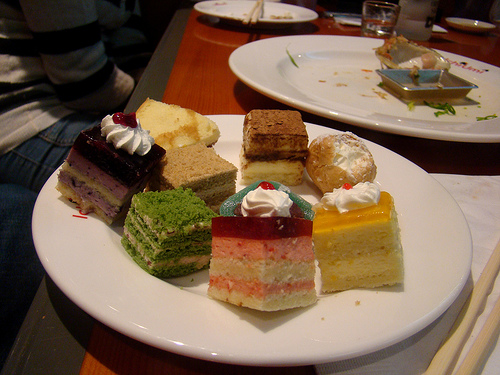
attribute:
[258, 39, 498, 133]
plate — empty, white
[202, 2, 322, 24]
plate — empty, white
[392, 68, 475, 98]
cup — metal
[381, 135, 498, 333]
plate — white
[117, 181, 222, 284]
pettifor — green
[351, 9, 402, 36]
glass — clear, empty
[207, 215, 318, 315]
cake — Red 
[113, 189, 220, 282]
cake — green, layered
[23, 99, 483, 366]
plate — white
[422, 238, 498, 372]
chopstick — wooden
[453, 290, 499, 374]
chopstick — wooden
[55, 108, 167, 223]
pastry — purple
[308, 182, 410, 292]
cake — Yellow 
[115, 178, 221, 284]
dessert — green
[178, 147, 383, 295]
cake — white , Green 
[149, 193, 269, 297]
cake — white, green 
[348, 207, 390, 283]
dessert — yellow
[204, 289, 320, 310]
layer — white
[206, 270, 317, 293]
layer — pink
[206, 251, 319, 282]
layer — white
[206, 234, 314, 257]
layer — pink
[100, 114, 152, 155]
cream — whipped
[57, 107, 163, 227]
dessert — purple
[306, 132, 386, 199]
dessert — brown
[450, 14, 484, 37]
saucer — white